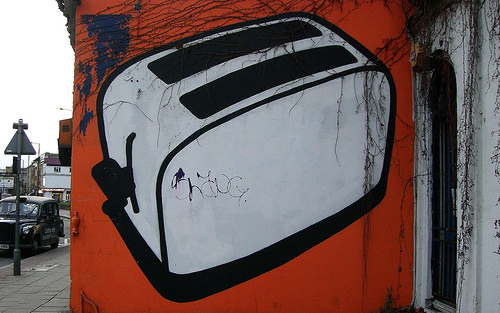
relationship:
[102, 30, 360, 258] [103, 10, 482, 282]
painting on wall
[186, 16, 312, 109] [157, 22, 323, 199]
slots in toaster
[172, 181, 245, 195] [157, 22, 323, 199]
writing on toaster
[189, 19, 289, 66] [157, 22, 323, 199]
openings of toaster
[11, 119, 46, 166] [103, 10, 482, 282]
sign by wall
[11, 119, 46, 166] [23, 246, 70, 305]
sign on sidewalk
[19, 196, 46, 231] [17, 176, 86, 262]
car on road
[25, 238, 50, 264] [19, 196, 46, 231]
tire on car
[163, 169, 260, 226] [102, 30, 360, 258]
signature on painting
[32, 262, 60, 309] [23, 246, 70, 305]
cracks in sidewalk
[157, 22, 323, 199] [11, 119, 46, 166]
toaster on sign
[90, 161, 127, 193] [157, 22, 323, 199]
handle on toaster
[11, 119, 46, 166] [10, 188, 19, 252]
sign with signpost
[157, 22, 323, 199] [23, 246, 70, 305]
toaster on sidewalk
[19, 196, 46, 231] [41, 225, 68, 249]
car has letting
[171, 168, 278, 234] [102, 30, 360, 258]
kwg on painting